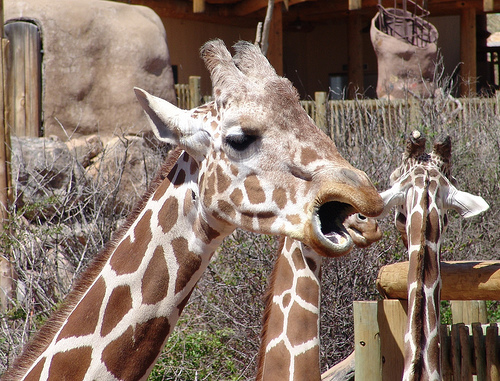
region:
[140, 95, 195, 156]
ear on giraffe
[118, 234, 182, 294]
spots on giraffe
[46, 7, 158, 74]
large rock behind giraffe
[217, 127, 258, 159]
eye on giraffe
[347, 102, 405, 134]
fenced area for giraffe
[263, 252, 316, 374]
neck of giraffe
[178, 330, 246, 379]
grass and branches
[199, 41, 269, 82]
antler like protrusions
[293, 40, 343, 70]
portion of a wall where giraffes are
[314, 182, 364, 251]
mouth opening of tall giraffe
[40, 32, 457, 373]
Giraffes are in the photo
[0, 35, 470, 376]
The photo was taken during the day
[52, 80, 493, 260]
A fence surrounds the giraffes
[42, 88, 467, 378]
The giraffes have brown spots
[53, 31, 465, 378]
Giraffes are facing different directions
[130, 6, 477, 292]
A building is in the background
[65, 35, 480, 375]
Giraffes have long necks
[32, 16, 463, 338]
It is sunny outside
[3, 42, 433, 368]
Photo was taken outside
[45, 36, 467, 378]
Photo was taken outdoors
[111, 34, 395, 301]
A giraffe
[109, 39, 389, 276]
A giraffe with an open mouth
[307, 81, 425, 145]
A wooden fence in the background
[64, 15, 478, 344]
Three giraffes in a zoo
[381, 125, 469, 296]
The back of a giraffes head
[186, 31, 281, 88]
The horns of a giraffe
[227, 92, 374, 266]
The face of a giraffe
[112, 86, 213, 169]
The ear of a giraffe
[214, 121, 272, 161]
The eye of a giraffe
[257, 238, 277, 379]
The mane of a giraffe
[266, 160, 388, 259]
The giraffe's mouth is open.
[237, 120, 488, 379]
Two giraffes are behind the first one.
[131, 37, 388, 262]
The giraffe is facing right.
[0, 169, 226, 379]
The giraffe's neck is brown and white.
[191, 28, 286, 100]
The giraffe has two horns.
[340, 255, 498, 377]
A fence is behind the giraffes.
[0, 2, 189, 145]
A boulder is behind the fence.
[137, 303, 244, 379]
Shrubs are behind the giraffes.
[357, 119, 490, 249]
The back of the giraffe's head is visible.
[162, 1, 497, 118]
A building is in the background.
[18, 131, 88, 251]
this is a dry vegetation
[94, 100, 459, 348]
these are giraffe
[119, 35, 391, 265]
the giraffe has opened its mouth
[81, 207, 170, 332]
the is the giraffe fur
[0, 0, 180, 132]
this is a stone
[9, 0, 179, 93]
the stone is big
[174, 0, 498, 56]
this is a house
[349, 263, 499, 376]
this is a fence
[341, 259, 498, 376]
the fence is made of woods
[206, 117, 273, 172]
this is a giraffe eyes